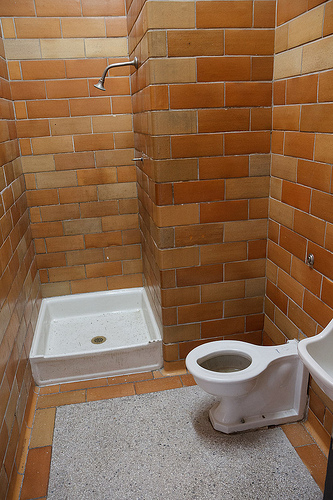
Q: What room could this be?
A: It is a bathroom.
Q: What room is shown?
A: It is a bathroom.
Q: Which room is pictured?
A: It is a bathroom.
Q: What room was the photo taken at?
A: It was taken at the bathroom.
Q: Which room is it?
A: It is a bathroom.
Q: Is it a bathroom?
A: Yes, it is a bathroom.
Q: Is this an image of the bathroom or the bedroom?
A: It is showing the bathroom.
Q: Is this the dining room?
A: No, it is the bathroom.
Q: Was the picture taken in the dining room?
A: No, the picture was taken in the bathroom.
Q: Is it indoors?
A: Yes, it is indoors.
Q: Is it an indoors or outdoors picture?
A: It is indoors.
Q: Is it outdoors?
A: No, it is indoors.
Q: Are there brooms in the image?
A: No, there are no brooms.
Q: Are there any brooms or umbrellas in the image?
A: No, there are no brooms or umbrellas.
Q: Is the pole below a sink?
A: Yes, the pole is below a sink.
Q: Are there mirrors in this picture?
A: No, there are no mirrors.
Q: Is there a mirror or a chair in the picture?
A: No, there are no mirrors or chairs.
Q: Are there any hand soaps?
A: No, there are no hand soaps.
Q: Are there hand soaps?
A: No, there are no hand soaps.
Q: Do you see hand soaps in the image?
A: No, there are no hand soaps.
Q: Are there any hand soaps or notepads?
A: No, there are no hand soaps or notepads.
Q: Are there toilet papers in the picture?
A: No, there are no toilet papers.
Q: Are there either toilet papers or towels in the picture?
A: No, there are no toilet papers or towels.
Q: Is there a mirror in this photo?
A: No, there are no mirrors.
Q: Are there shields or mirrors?
A: No, there are no mirrors or shields.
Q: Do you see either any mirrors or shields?
A: No, there are no mirrors or shields.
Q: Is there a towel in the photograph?
A: No, there are no towels.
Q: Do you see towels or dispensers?
A: No, there are no towels or dispensers.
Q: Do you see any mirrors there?
A: No, there are no mirrors.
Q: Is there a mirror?
A: No, there are no mirrors.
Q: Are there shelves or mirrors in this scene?
A: No, there are no mirrors or shelves.